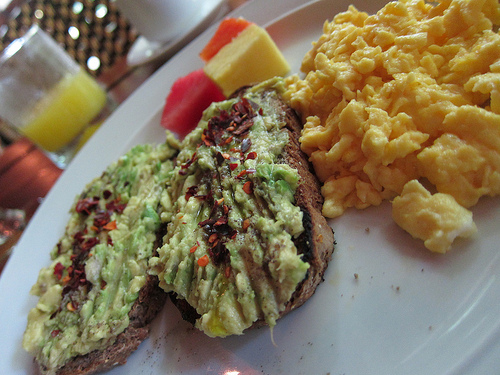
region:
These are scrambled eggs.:
[290, 6, 498, 219]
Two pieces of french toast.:
[23, 97, 322, 372]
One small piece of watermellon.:
[160, 68, 218, 137]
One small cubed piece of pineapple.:
[205, 4, 286, 107]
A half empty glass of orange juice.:
[0, 24, 129, 149]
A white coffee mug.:
[116, 1, 231, 55]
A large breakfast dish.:
[2, 4, 498, 373]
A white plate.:
[3, 10, 489, 372]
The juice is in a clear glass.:
[0, 6, 110, 162]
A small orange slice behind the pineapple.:
[175, 16, 263, 52]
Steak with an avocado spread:
[27, 84, 322, 364]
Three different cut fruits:
[130, 9, 288, 136]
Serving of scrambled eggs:
[287, 0, 498, 250]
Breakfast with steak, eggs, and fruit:
[24, 0, 499, 361]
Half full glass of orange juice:
[0, 19, 113, 153]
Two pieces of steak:
[17, 93, 320, 365]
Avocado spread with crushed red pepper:
[159, 83, 319, 340]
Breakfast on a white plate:
[50, 0, 497, 367]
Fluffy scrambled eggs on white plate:
[277, 0, 497, 264]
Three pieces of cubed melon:
[158, 12, 292, 139]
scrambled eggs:
[295, 2, 492, 246]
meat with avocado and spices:
[21, 139, 341, 321]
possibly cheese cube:
[203, 20, 290, 85]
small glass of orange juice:
[5, 38, 108, 153]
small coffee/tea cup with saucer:
[101, 0, 223, 66]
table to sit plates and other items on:
[3, 153, 47, 186]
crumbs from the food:
[349, 261, 404, 295]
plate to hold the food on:
[333, 253, 477, 367]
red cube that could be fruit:
[156, 69, 213, 129]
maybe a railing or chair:
[7, 0, 114, 23]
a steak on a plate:
[19, 54, 374, 373]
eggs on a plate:
[35, 23, 494, 374]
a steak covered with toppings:
[17, 40, 397, 374]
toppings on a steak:
[9, 61, 394, 373]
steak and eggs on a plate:
[8, 26, 493, 373]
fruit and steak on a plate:
[43, 28, 385, 348]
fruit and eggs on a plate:
[152, 14, 462, 225]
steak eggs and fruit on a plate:
[32, 13, 498, 371]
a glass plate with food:
[23, 58, 476, 333]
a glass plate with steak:
[27, 43, 464, 353]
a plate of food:
[35, 28, 498, 370]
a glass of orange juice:
[3, 37, 118, 156]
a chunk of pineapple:
[210, 30, 312, 90]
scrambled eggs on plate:
[283, 27, 498, 252]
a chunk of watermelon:
[155, 70, 248, 147]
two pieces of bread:
[21, 94, 361, 366]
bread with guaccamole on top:
[41, 137, 364, 341]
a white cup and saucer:
[107, 1, 204, 65]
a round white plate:
[5, 3, 498, 373]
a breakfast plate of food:
[37, 30, 485, 367]